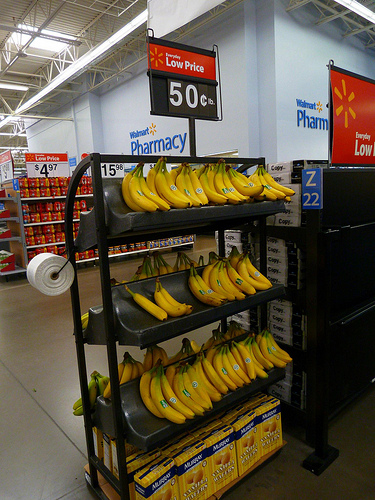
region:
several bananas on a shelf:
[96, 147, 299, 228]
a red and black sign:
[128, 25, 231, 121]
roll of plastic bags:
[21, 239, 77, 321]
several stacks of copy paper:
[263, 155, 299, 288]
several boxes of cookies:
[156, 391, 286, 498]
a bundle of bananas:
[114, 158, 149, 223]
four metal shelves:
[3, 164, 110, 280]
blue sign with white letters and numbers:
[287, 159, 323, 210]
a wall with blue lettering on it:
[64, 54, 251, 165]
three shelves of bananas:
[39, 69, 332, 455]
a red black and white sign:
[142, 28, 224, 121]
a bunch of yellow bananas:
[139, 355, 198, 425]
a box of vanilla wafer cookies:
[173, 447, 221, 498]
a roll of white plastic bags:
[24, 237, 77, 298]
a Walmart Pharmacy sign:
[128, 126, 197, 158]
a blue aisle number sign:
[299, 166, 322, 209]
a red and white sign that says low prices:
[327, 114, 374, 162]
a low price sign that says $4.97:
[24, 153, 72, 176]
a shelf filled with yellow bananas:
[70, 148, 288, 400]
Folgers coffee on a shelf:
[20, 174, 62, 197]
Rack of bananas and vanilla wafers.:
[58, 141, 301, 498]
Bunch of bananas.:
[118, 161, 168, 210]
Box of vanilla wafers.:
[255, 395, 283, 458]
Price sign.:
[144, 25, 225, 123]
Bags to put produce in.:
[25, 248, 76, 298]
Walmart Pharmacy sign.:
[126, 121, 188, 154]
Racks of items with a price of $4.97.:
[21, 146, 146, 268]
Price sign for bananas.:
[144, 25, 223, 120]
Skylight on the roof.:
[4, 11, 80, 55]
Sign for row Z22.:
[301, 169, 324, 209]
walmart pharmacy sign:
[115, 114, 243, 184]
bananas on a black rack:
[108, 120, 310, 435]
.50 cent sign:
[127, 16, 255, 148]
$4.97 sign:
[13, 140, 86, 207]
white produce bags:
[7, 231, 111, 308]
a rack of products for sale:
[4, 153, 249, 286]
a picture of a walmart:
[26, 25, 374, 292]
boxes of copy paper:
[233, 147, 334, 378]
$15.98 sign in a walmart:
[66, 140, 151, 188]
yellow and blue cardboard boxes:
[131, 384, 330, 493]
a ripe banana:
[124, 290, 169, 323]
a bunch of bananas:
[119, 164, 290, 206]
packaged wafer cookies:
[205, 430, 237, 488]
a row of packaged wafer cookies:
[151, 397, 285, 498]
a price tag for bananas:
[151, 50, 218, 122]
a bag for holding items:
[23, 245, 79, 303]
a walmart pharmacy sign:
[121, 126, 191, 151]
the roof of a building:
[12, 19, 113, 68]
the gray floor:
[15, 305, 58, 414]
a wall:
[290, 37, 320, 82]